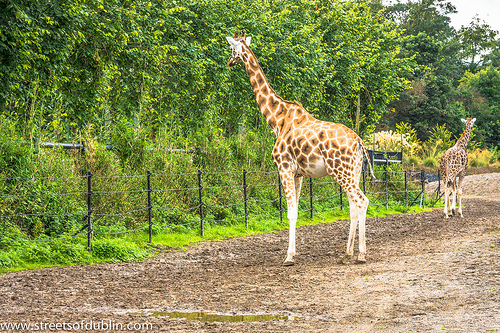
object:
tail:
[356, 129, 377, 182]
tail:
[441, 152, 451, 188]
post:
[438, 167, 441, 206]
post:
[360, 170, 367, 210]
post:
[336, 181, 344, 211]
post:
[305, 172, 315, 216]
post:
[276, 168, 288, 229]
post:
[241, 168, 251, 228]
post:
[195, 168, 207, 238]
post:
[143, 170, 155, 242]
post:
[83, 170, 93, 248]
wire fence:
[4, 157, 441, 266]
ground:
[437, 142, 464, 170]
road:
[128, 220, 499, 332]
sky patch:
[448, 26, 498, 69]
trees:
[437, 28, 497, 120]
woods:
[20, 13, 209, 138]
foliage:
[12, 42, 14, 44]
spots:
[265, 114, 347, 165]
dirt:
[386, 215, 493, 321]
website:
[6, 317, 163, 330]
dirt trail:
[0, 198, 500, 332]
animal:
[436, 115, 476, 221]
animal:
[225, 31, 376, 266]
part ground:
[55, 263, 179, 301]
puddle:
[126, 298, 298, 330]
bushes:
[79, 124, 129, 220]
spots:
[291, 140, 355, 180]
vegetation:
[1, 118, 420, 258]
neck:
[243, 53, 290, 125]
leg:
[353, 186, 371, 264]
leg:
[336, 194, 356, 264]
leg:
[277, 165, 300, 267]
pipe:
[27, 142, 402, 163]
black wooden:
[310, 176, 313, 219]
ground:
[395, 272, 451, 308]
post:
[191, 173, 212, 238]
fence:
[0, 169, 440, 254]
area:
[0, 0, 499, 332]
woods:
[0, 0, 498, 270]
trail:
[6, 173, 496, 330]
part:
[390, 274, 423, 323]